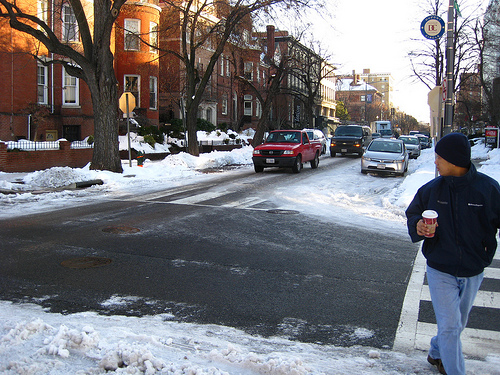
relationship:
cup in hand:
[410, 206, 443, 244] [405, 216, 435, 237]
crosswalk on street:
[59, 161, 413, 363] [92, 204, 370, 324]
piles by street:
[126, 148, 231, 186] [46, 204, 367, 333]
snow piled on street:
[163, 150, 201, 179] [109, 185, 291, 285]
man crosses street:
[399, 117, 491, 368] [59, 161, 413, 363]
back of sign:
[112, 92, 143, 120] [96, 87, 153, 122]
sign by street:
[96, 87, 153, 122] [59, 161, 413, 363]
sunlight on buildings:
[1, 3, 204, 79] [1, 0, 264, 161]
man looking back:
[399, 117, 491, 368] [401, 122, 490, 202]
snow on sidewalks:
[0, 156, 233, 202] [0, 140, 210, 219]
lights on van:
[325, 139, 367, 156] [329, 121, 372, 150]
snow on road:
[59, 161, 413, 363] [0, 192, 374, 338]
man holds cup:
[399, 117, 491, 368] [410, 206, 443, 244]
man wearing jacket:
[399, 117, 491, 368] [402, 165, 496, 269]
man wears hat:
[399, 117, 491, 368] [432, 129, 487, 170]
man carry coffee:
[399, 117, 491, 368] [410, 206, 443, 244]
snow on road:
[0, 156, 233, 202] [0, 192, 374, 338]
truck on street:
[244, 115, 332, 178] [59, 161, 413, 363]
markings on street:
[216, 172, 265, 225] [59, 161, 413, 363]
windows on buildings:
[119, 13, 159, 109] [1, 0, 264, 161]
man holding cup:
[399, 117, 491, 368] [410, 206, 443, 244]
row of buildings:
[1, 10, 400, 113] [1, 0, 264, 161]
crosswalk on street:
[364, 244, 458, 358] [59, 161, 413, 363]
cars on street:
[229, 103, 423, 205] [59, 161, 413, 363]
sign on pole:
[411, 15, 444, 43] [432, 39, 447, 104]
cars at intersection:
[229, 103, 423, 205] [47, 96, 443, 262]